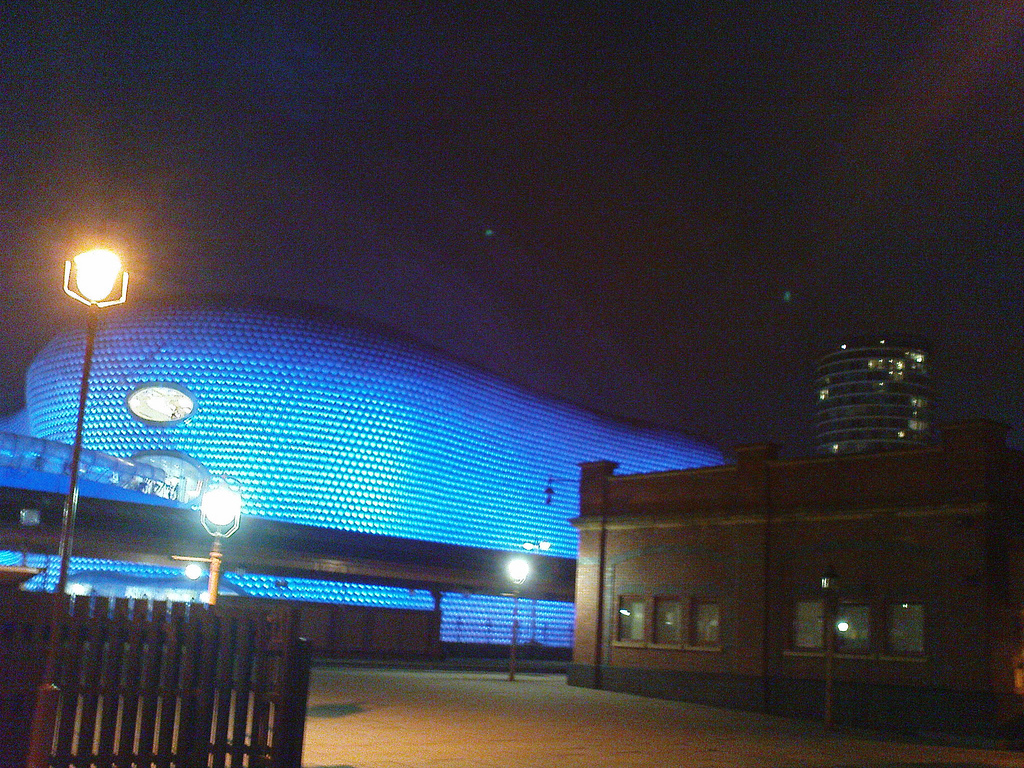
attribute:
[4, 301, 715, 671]
building — blue lit up 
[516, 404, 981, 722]
building — blue 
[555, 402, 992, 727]
building — circular tall 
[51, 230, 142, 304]
light — yellow 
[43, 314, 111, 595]
pole — yellow 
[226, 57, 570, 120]
sky — dark 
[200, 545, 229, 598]
post — yellow cement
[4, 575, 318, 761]
fence — picket , brown, wooden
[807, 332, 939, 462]
building — tall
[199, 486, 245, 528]
light — bright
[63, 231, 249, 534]
lights — bright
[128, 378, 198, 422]
light — oval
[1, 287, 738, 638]
building — very large, blue